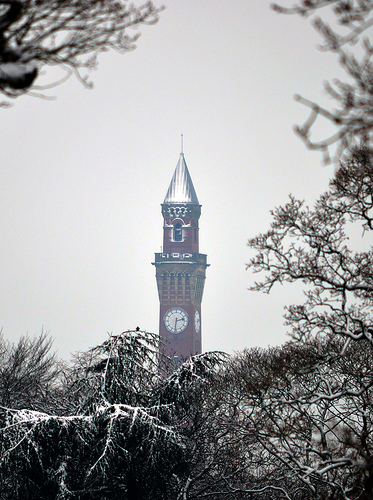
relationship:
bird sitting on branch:
[132, 323, 142, 333] [117, 330, 168, 348]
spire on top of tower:
[176, 131, 190, 156] [142, 121, 216, 358]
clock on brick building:
[194, 308, 201, 334] [155, 204, 206, 369]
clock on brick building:
[163, 305, 189, 335] [155, 204, 206, 369]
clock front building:
[161, 308, 188, 334] [148, 124, 211, 376]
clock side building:
[190, 308, 203, 333] [149, 129, 210, 358]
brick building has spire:
[150, 132, 210, 375] [155, 131, 204, 205]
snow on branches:
[3, 388, 182, 450] [5, 324, 236, 499]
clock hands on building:
[162, 306, 193, 335] [148, 124, 211, 376]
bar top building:
[180, 131, 183, 153] [151, 132, 210, 452]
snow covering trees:
[20, 402, 70, 427] [5, 336, 370, 499]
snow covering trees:
[338, 327, 363, 336] [1, 1, 162, 107]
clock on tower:
[163, 305, 189, 335] [151, 130, 210, 380]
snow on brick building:
[165, 188, 187, 200] [150, 132, 210, 375]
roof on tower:
[163, 152, 199, 205] [149, 146, 215, 380]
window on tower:
[172, 220, 183, 243] [148, 129, 212, 494]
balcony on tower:
[151, 250, 210, 265] [150, 133, 209, 476]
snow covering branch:
[0, 156, 371, 497] [237, 208, 365, 322]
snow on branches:
[15, 395, 176, 457] [1, 0, 371, 466]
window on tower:
[169, 220, 186, 243] [144, 110, 225, 371]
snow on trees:
[30, 328, 252, 444] [31, 332, 180, 434]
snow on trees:
[30, 328, 252, 444] [271, 324, 366, 454]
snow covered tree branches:
[93, 391, 170, 434] [275, 241, 335, 321]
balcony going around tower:
[151, 250, 212, 266] [151, 130, 210, 380]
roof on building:
[163, 152, 199, 205] [139, 125, 214, 448]